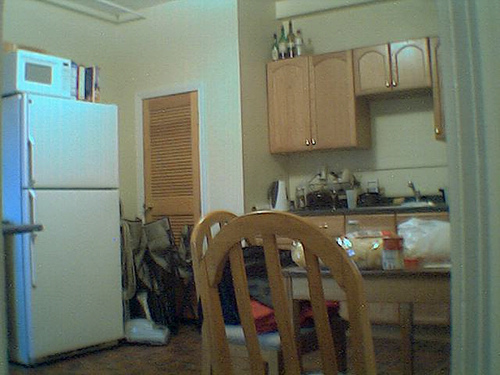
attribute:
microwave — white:
[0, 45, 76, 103]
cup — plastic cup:
[346, 187, 358, 212]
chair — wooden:
[197, 211, 379, 373]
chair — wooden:
[188, 209, 350, 371]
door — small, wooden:
[135, 92, 206, 235]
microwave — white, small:
[4, 47, 76, 99]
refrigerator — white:
[5, 93, 129, 363]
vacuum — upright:
[106, 249, 171, 346]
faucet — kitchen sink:
[400, 176, 430, 203]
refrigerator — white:
[13, 82, 173, 361]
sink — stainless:
[381, 200, 448, 210]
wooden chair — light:
[173, 199, 410, 371]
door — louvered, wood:
[139, 88, 201, 248]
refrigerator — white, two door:
[10, 97, 125, 350]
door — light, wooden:
[114, 78, 261, 303]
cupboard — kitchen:
[266, 47, 370, 155]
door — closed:
[264, 54, 314, 156]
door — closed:
[309, 47, 359, 152]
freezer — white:
[19, 96, 124, 187]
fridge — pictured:
[1, 90, 123, 360]